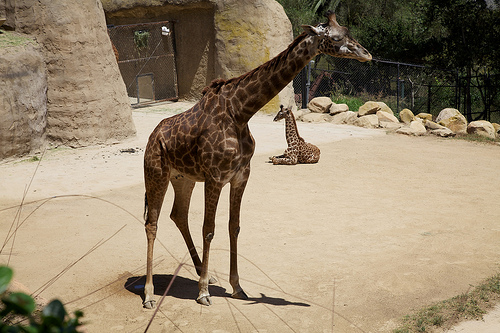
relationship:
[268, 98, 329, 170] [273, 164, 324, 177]
giraffe on ground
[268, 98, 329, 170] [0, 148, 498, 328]
giraffe on ground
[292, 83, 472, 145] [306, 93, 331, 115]
pile of stone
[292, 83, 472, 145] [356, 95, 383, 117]
pile of stone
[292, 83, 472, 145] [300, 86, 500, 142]
pile of rock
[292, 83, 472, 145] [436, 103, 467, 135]
pile of stone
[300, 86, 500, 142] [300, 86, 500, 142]
rock next to rock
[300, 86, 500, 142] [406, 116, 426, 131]
rock next to rock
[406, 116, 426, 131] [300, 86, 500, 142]
rock next to rock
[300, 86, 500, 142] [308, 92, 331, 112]
rock next to rock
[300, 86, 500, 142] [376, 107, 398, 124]
rock next to rock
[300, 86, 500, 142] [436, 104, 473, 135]
rock next to rock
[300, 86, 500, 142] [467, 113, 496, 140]
rock next to rock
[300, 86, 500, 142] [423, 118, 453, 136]
rock next to rock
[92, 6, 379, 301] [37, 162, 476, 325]
giraffe on ground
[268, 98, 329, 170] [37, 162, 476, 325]
giraffe on ground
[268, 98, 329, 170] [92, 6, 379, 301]
giraffe on giraffe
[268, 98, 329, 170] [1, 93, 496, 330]
giraffe on ground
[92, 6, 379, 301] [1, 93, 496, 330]
giraffe on ground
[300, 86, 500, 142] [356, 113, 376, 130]
rock next to rock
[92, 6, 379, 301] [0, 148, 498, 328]
giraffe on ground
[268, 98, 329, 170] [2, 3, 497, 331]
giraffe in zoo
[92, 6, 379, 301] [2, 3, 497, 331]
giraffe in zoo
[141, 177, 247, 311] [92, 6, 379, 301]
legs of giraffe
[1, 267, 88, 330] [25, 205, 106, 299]
plants in foreground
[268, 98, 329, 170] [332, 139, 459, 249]
giraffe laying down on ground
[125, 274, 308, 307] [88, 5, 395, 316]
shadow of giraffe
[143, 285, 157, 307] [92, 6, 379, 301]
feet of giraffe